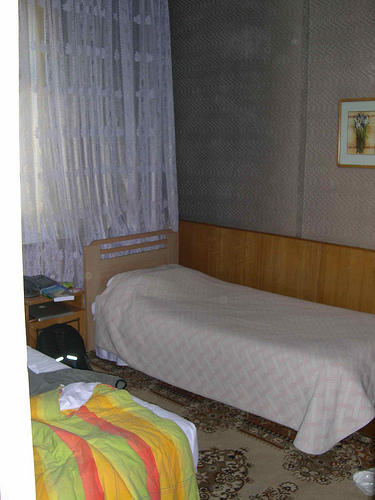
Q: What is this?
A: Bed.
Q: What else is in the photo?
A: Curtain.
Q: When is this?
A: Daytime.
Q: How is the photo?
A: Clean.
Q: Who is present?
A: No one.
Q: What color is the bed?
A: Brown.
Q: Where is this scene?
A: Bedroom.